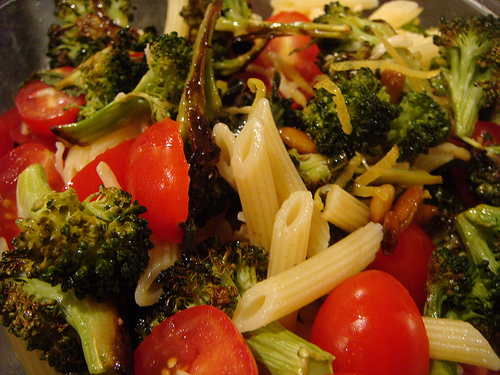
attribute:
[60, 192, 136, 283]
broccoli — green, fresh, well done, black, lush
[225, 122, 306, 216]
pasta — cooked, yellow, penne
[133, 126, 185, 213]
tomato — red, cut, half, sliced, cherry tomato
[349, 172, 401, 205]
cheese — shredded, melted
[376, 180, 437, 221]
bean — red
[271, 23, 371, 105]
vegetable — varied, green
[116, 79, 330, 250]
food — oily, pasta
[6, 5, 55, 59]
background — grey